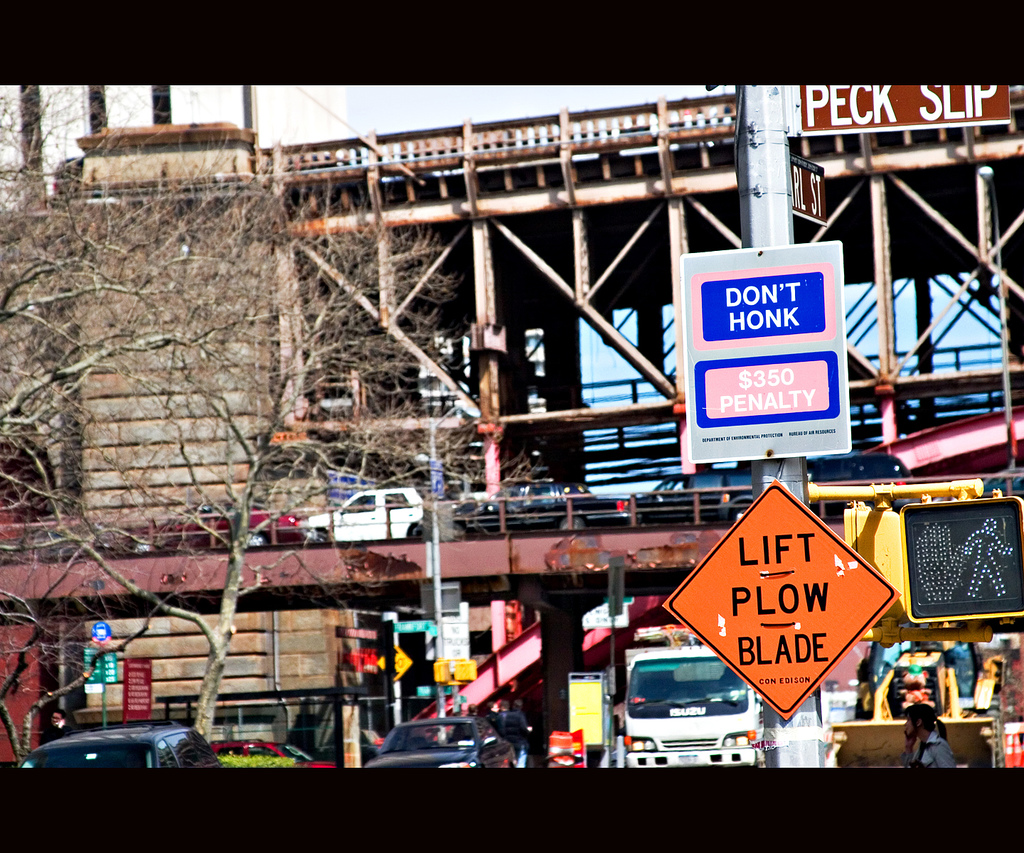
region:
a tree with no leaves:
[8, 137, 465, 735]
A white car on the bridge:
[294, 478, 443, 554]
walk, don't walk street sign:
[898, 492, 1022, 620]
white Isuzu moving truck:
[620, 649, 821, 763]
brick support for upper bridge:
[73, 125, 356, 764]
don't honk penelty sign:
[678, 238, 850, 458]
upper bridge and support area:
[3, 102, 1022, 461]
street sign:
[81, 643, 117, 681]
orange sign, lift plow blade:
[657, 478, 898, 723]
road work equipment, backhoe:
[827, 621, 1006, 768]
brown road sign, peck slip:
[793, 80, 1010, 131]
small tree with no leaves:
[0, 83, 552, 754]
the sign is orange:
[631, 479, 848, 824]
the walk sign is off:
[897, 501, 1021, 641]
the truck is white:
[612, 637, 761, 771]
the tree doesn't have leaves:
[49, 189, 389, 731]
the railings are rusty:
[333, 135, 660, 455]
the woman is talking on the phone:
[886, 708, 954, 763]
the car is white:
[302, 477, 440, 554]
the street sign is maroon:
[794, 81, 1022, 145]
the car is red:
[214, 726, 309, 781]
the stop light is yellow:
[418, 656, 510, 679]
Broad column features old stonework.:
[75, 205, 300, 542]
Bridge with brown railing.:
[107, 122, 819, 265]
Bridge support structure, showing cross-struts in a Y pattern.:
[287, 233, 1022, 436]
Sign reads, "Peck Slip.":
[799, 82, 1022, 187]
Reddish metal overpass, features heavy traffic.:
[51, 464, 881, 665]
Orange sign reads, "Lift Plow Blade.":
[704, 499, 848, 759]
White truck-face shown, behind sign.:
[625, 637, 771, 814]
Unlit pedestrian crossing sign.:
[897, 505, 1015, 594]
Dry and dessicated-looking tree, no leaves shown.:
[34, 148, 398, 768]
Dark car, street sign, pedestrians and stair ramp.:
[383, 641, 551, 791]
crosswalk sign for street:
[898, 497, 1022, 621]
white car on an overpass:
[291, 482, 441, 543]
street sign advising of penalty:
[678, 245, 852, 460]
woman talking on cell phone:
[891, 697, 964, 771]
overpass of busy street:
[3, 513, 718, 581]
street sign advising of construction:
[657, 482, 904, 716]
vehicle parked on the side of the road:
[360, 712, 519, 774]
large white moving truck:
[620, 646, 767, 768]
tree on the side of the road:
[12, 220, 355, 746]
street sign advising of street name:
[790, 84, 1015, 129]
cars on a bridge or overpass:
[3, 437, 908, 539]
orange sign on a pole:
[685, 485, 867, 751]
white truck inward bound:
[615, 634, 764, 777]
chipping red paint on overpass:
[476, 530, 711, 575]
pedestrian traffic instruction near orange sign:
[834, 469, 1022, 628]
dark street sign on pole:
[755, 77, 1011, 136]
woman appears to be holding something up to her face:
[884, 694, 971, 768]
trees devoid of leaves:
[21, 200, 335, 675]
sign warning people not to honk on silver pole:
[686, 210, 849, 452]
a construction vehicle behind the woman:
[828, 637, 1006, 765]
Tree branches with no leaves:
[62, 204, 338, 516]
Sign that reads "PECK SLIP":
[786, 79, 1010, 153]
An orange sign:
[657, 465, 893, 702]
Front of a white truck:
[610, 627, 805, 765]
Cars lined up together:
[136, 473, 787, 562]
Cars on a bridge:
[62, 460, 672, 647]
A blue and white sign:
[618, 214, 875, 487]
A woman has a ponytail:
[872, 690, 981, 764]